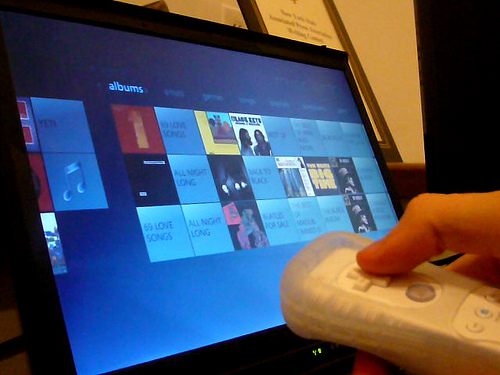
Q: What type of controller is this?
A: Wii.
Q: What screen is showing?
A: Albums.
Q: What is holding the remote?
A: A hand.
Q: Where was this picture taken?
A: Inside of a house.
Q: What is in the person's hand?
A: A controller.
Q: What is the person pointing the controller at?
A: A television.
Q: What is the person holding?
A: Wii remote.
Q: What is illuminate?
A: The screen.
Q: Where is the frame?
A: On the wall.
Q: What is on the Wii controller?
A: Remote skin.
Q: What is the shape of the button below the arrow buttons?
A: Round.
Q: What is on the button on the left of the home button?
A: Minus sign.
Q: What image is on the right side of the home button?
A: The + button.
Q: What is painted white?
A: A wall.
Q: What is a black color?
A: A television.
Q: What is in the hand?
A: A Wii controller.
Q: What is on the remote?
A: Thumb.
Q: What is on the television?
A: Icons.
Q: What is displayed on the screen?
A: Music choices.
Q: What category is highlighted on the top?
A: Albums.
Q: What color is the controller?
A: White.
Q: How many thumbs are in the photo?
A: 1.